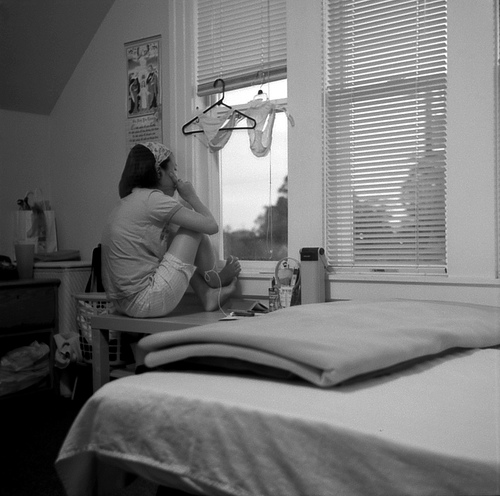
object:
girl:
[108, 136, 245, 321]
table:
[90, 302, 268, 394]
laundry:
[64, 293, 122, 361]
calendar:
[123, 31, 165, 156]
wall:
[55, 12, 169, 225]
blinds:
[325, 6, 455, 20]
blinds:
[193, 3, 280, 15]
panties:
[197, 108, 245, 151]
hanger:
[178, 78, 258, 136]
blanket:
[134, 297, 498, 390]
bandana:
[138, 140, 173, 169]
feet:
[201, 276, 239, 315]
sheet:
[58, 352, 498, 494]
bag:
[11, 195, 62, 260]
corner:
[14, 93, 89, 270]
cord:
[205, 255, 227, 316]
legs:
[147, 222, 241, 319]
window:
[189, 4, 294, 270]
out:
[195, 89, 308, 257]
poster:
[125, 36, 165, 172]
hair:
[116, 139, 173, 197]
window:
[320, 7, 455, 271]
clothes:
[79, 299, 116, 346]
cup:
[14, 240, 36, 281]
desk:
[3, 275, 61, 375]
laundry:
[36, 259, 95, 350]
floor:
[1, 372, 117, 492]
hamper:
[20, 256, 115, 338]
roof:
[6, 3, 127, 126]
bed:
[74, 299, 499, 494]